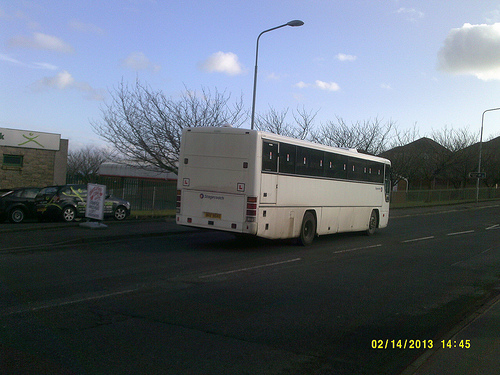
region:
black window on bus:
[263, 135, 279, 170]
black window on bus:
[278, 144, 293, 172]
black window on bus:
[295, 145, 307, 175]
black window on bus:
[309, 150, 323, 173]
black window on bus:
[322, 153, 334, 175]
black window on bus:
[334, 157, 347, 175]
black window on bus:
[345, 157, 357, 179]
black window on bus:
[357, 161, 368, 179]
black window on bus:
[365, 161, 371, 178]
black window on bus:
[374, 162, 382, 184]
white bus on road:
[194, 106, 404, 272]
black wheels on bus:
[282, 217, 385, 242]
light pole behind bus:
[230, 10, 299, 135]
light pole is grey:
[240, 20, 303, 129]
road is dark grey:
[305, 235, 437, 346]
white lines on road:
[294, 233, 440, 302]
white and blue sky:
[276, 3, 477, 126]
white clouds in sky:
[279, 13, 494, 88]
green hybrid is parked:
[37, 164, 119, 220]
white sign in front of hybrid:
[76, 171, 102, 227]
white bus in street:
[171, 124, 391, 243]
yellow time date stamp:
[366, 335, 471, 352]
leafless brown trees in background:
[68, 80, 480, 216]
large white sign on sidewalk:
[82, 181, 110, 229]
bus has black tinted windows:
[258, 139, 390, 182]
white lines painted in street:
[6, 220, 497, 317]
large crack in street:
[66, 304, 386, 374]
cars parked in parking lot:
[3, 185, 132, 220]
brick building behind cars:
[1, 129, 68, 201]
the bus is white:
[164, 109, 444, 252]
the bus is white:
[166, 123, 398, 245]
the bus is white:
[154, 116, 414, 267]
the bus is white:
[172, 120, 398, 241]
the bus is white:
[167, 125, 398, 249]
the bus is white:
[162, 120, 403, 249]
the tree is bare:
[95, 97, 188, 169]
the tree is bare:
[118, 106, 201, 164]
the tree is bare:
[88, 91, 211, 196]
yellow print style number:
[370, 335, 378, 350]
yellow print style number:
[375, 337, 385, 352]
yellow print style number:
[387, 338, 397, 350]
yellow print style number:
[394, 337, 404, 349]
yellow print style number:
[407, 335, 417, 347]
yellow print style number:
[414, 338, 421, 350]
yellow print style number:
[420, 337, 427, 350]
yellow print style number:
[424, 336, 434, 351]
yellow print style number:
[439, 338, 446, 350]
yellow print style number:
[443, 338, 453, 351]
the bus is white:
[176, 124, 393, 239]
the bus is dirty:
[176, 125, 390, 243]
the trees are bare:
[3, 73, 498, 198]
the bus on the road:
[1, 125, 496, 374]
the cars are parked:
[2, 182, 129, 227]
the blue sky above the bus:
[1, 0, 498, 247]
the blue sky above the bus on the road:
[1, 0, 499, 374]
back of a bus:
[180, 124, 258, 234]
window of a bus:
[262, 136, 278, 171]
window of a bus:
[280, 145, 292, 167]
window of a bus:
[310, 150, 322, 172]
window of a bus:
[331, 156, 341, 176]